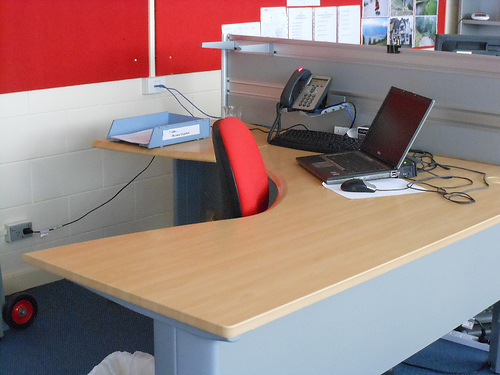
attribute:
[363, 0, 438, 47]
pictures — colorful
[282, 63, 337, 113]
telephone — black, grey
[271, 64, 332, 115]
telephone — black, gray, landline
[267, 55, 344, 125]
phone — silver, grey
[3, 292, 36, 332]
wheel — red, black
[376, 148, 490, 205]
cord — black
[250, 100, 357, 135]
cord — black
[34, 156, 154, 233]
cord — black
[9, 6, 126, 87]
bulletin board — empty, red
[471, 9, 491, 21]
clock — white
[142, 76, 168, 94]
outlet — silver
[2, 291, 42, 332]
wheel — red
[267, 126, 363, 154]
keyboard — black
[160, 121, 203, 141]
sticker — white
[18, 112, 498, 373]
desk — brown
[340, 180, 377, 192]
mouse —  black and grey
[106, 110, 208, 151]
tray — blue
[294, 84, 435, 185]
computer — grey, laptop, open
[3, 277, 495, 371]
carpet — blue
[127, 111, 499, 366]
desk — clean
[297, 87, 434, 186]
laptop — computer, screen, open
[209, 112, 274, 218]
chair — red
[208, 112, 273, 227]
chair — red, black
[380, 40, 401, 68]
clamp — black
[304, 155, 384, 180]
keyboard — black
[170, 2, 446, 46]
bulletin board — red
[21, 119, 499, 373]
office desk — minimal, scene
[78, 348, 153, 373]
bag — white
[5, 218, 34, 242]
outlet — wall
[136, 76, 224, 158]
inbox — blue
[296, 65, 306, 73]
light — red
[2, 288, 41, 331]
tire — black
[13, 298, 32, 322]
inner tire — red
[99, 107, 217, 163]
holder — silver, paper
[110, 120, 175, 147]
paper — white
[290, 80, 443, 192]
laptop — open